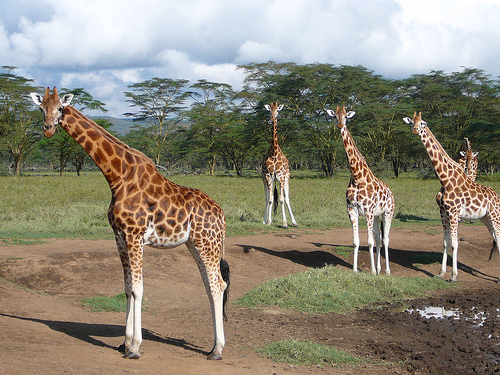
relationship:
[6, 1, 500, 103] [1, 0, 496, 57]
cloud in sky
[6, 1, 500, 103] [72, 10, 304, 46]
cloud in sky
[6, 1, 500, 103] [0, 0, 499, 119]
cloud in blue sky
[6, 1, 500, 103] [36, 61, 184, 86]
cloud in blue sky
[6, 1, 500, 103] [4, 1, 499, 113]
cloud in sky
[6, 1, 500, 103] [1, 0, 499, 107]
cloud in blue sky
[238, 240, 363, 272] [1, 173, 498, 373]
shadow on ground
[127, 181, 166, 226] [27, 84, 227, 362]
spots on giraffe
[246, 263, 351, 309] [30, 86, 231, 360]
grass growing by giraffe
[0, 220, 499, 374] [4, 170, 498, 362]
dirt patches in grass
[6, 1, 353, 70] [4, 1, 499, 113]
cloud in sky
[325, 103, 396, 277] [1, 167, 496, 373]
giraffe in field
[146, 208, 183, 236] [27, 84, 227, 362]
spots on giraffe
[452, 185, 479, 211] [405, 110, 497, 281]
spots on giraffe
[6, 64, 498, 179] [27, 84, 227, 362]
trees behind giraffe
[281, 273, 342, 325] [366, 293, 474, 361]
grass next to mud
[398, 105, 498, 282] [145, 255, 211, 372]
giraffe standing in dirt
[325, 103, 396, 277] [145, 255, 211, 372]
giraffe standing in dirt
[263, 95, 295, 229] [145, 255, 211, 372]
giraffe standing in dirt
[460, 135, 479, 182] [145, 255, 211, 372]
giraffe standing in dirt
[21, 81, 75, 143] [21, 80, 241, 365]
head of giraffe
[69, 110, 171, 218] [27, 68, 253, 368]
neck of giraffe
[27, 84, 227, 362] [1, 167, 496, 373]
giraffe in field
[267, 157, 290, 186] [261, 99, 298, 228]
spots on giraffe